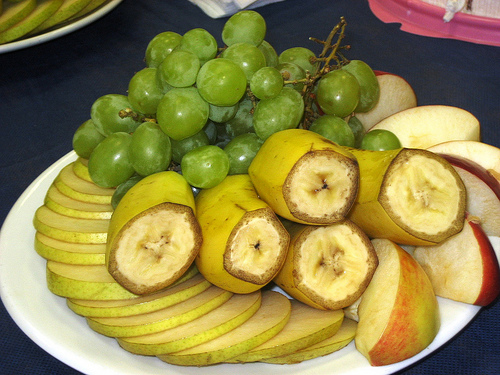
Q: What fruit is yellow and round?
A: Banana.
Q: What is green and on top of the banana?
A: Grapes.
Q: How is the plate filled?
A: With fruits.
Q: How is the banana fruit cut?
A: Into pieces.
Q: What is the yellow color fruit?
A: Bananas.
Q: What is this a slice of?
A: An apple.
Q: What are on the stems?
A: Grapes.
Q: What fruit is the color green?
A: Grapes.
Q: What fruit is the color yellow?
A: Apple slices.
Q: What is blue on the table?
A: The table cloth.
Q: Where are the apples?
A: On the plate.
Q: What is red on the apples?
A: The skin.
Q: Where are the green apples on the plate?
A: On the left side.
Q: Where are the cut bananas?
A: In the middle of the plate.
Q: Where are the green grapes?
A: Behind the bananas.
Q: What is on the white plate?
A: Fruit.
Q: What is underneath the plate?
A: A blue tablecloth.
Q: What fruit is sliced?
A: The apples.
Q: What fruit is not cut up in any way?
A: The grapes.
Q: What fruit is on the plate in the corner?
A: Green apples.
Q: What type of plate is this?
A: A fruit plate.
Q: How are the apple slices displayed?
A: In a row.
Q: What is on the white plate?
A: Fruit.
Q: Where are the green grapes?
A: On the plate.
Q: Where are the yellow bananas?
A: On the plate.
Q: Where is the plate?
A: On a table.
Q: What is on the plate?
A: Fruit.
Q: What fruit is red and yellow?
A: Apple.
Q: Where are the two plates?
A: On the table.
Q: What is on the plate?
A: Fruits.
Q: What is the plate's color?
A: White.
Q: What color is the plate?
A: White.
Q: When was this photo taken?
A: During a mealtime.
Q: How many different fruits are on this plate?
A: Four.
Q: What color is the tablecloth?
A: Blue.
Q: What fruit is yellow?
A: Bananas.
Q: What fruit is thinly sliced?
A: Pears.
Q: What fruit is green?
A: Grapes.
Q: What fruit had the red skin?
A: Apples.